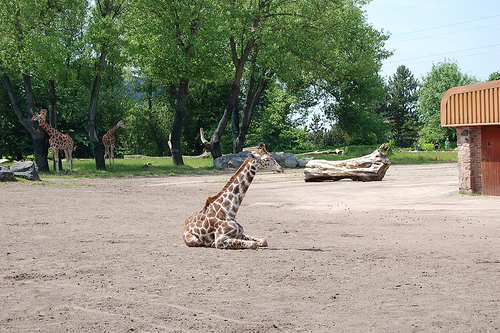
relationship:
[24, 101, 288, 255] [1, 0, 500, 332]
giraffes are in park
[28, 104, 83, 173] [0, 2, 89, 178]
giraffe by a tree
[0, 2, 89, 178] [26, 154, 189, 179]
tree in grass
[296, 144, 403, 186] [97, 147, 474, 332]
tree stump on ground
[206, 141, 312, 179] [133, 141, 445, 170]
rocks are in grass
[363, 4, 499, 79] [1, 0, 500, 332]
sky in park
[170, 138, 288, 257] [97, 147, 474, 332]
giraffe on ground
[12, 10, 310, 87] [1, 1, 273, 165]
leaves are on trees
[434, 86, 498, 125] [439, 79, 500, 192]
roof on building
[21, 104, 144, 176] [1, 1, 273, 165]
giraffes are by trees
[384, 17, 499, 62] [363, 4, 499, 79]
powerlines are in sky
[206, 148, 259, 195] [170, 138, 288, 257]
mane on giraffe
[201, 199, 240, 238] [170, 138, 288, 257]
pattern on giraffe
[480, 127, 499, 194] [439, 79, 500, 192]
door on building